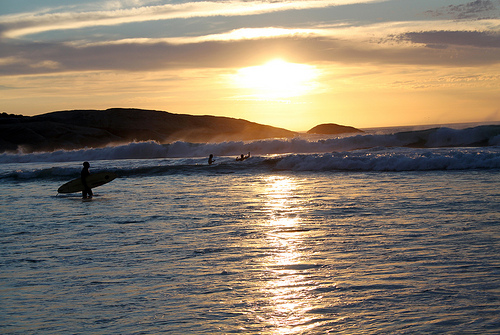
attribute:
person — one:
[58, 159, 119, 218]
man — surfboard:
[77, 154, 97, 204]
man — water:
[52, 150, 117, 214]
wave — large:
[6, 143, 481, 170]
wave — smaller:
[206, 149, 485, 186]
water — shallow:
[13, 140, 460, 330]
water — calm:
[18, 151, 483, 315]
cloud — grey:
[132, 46, 226, 77]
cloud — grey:
[35, 40, 147, 70]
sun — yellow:
[221, 48, 334, 115]